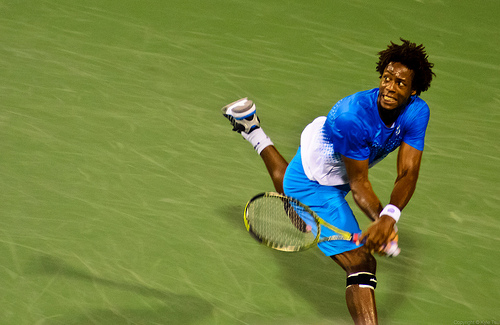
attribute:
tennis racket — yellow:
[242, 192, 399, 255]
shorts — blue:
[281, 144, 369, 258]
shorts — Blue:
[283, 146, 363, 256]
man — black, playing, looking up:
[220, 44, 436, 323]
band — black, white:
[346, 270, 387, 288]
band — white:
[362, 197, 446, 235]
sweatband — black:
[342, 271, 377, 291]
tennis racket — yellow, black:
[238, 185, 409, 257]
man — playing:
[249, 36, 419, 323]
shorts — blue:
[276, 147, 373, 252]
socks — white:
[237, 127, 274, 156]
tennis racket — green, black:
[219, 176, 395, 261]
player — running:
[239, 32, 472, 282]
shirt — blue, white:
[294, 84, 431, 191]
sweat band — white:
[375, 203, 401, 224]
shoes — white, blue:
[177, 62, 302, 179]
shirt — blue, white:
[300, 87, 430, 187]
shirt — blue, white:
[282, 80, 442, 195]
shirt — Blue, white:
[284, 62, 451, 214]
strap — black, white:
[343, 271, 380, 288]